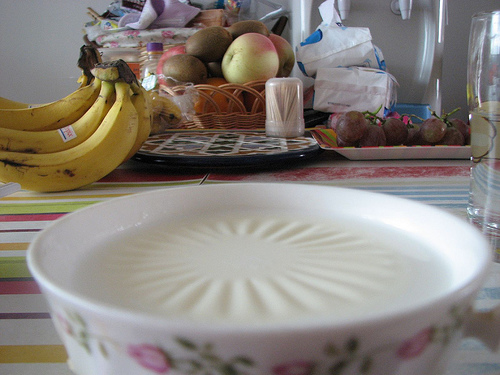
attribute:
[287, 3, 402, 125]
bags — stacked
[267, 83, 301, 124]
toothpicks — filled, wooden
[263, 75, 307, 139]
container — clear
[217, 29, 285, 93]
apple — red, green, colored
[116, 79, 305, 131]
basket — brown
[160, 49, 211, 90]
kiwi — ripe, fuzzy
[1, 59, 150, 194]
bananas — yellow, bundled, ripe, bunch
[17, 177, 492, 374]
dispenser — white, clear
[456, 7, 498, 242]
glass — filled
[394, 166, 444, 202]
cloth — colored, white, yellow, red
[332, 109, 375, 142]
grape — small, red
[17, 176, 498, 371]
bowl — white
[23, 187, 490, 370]
dish — white